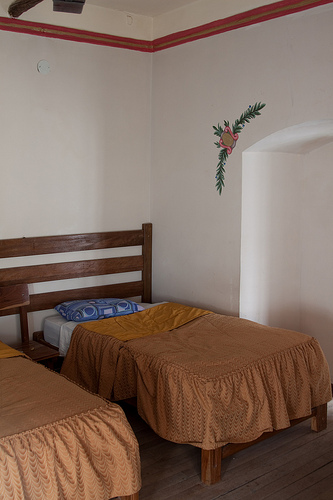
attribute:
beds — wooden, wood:
[0, 221, 332, 498]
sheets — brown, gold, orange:
[6, 303, 313, 481]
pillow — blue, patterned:
[49, 297, 148, 320]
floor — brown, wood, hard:
[99, 398, 331, 499]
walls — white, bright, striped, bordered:
[4, 0, 332, 358]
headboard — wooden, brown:
[0, 217, 158, 305]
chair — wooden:
[2, 281, 66, 370]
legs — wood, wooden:
[117, 392, 333, 499]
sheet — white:
[46, 312, 78, 349]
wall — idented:
[155, 15, 332, 347]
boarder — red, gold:
[2, 1, 331, 59]